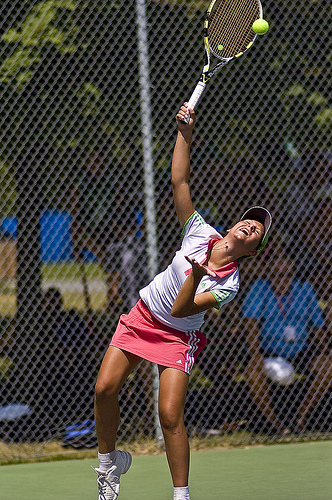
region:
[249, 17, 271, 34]
a green tennis ball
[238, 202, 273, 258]
a green and gray cap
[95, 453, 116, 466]
a white sock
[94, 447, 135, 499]
a woman's white tennis shoe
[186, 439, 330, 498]
part of a tennis court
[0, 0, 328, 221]
part of a chain link fence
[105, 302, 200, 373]
a woman's pink and white skirt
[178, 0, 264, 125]
a woman's black and yellow racket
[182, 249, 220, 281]
the hand of a woman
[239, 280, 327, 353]
a man's blue shirt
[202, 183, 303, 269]
face of the man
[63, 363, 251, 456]
legs of the girl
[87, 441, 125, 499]
shoe of the person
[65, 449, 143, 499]
a girl wearing shoes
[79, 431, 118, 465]
a girl wearing socks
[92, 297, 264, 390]
a girl wearing shirts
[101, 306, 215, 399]
a girl wearing pink shorts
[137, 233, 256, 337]
a girl wearing shirts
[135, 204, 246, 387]
a girl wearing t shirt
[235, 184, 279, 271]
a girl wearing cap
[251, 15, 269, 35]
tennis ball in air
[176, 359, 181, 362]
Addidas logo on girl's skirt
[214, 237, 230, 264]
necklace on girl's neck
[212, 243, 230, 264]
shadow of necklace on girl's neck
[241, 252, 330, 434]
man seated behind fence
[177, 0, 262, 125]
tennis racquet in girl's hand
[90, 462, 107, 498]
laces on right shoe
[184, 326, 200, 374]
white stripes on girl's skirt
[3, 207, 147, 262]
blue wall in background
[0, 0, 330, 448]
silver chain link fence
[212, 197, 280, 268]
head of a person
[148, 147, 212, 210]
arm of a person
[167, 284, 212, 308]
arm of a person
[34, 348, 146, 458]
leg of a person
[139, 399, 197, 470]
leg of a person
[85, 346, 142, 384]
thigh of a person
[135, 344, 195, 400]
thigh of a person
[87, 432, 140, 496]
feet of a person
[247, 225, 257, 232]
nose of a person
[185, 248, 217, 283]
hand of a person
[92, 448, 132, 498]
Woman wearing shoes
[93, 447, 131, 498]
Woman is wearing shoes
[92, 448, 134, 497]
Woman wearing white shoes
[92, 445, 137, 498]
Woman is wearing white shoes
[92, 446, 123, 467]
Woman wearing socks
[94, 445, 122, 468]
Woman is wearing socks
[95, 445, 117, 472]
Woman wearing white socks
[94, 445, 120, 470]
Woman is wearing white socks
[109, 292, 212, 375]
Woman wearing a pink and white skirt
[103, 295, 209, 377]
Woman is wearing a pink and white skirt